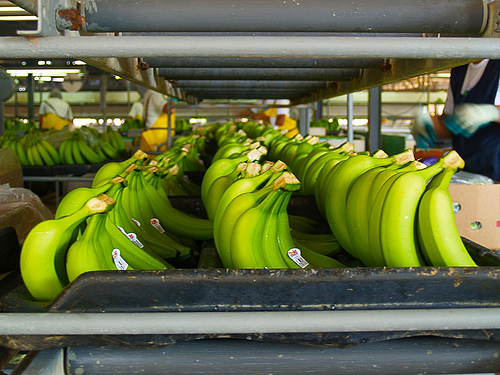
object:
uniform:
[442, 58, 500, 184]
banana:
[65, 196, 109, 284]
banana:
[113, 130, 127, 150]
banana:
[230, 176, 293, 269]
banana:
[324, 148, 413, 260]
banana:
[136, 153, 214, 241]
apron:
[263, 99, 299, 139]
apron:
[40, 100, 71, 130]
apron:
[139, 94, 176, 158]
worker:
[263, 99, 299, 139]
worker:
[137, 66, 176, 167]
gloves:
[410, 107, 438, 152]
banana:
[416, 157, 480, 267]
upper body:
[37, 97, 74, 119]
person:
[38, 88, 74, 131]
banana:
[31, 141, 44, 166]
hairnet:
[47, 87, 63, 99]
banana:
[54, 175, 126, 221]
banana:
[379, 150, 460, 269]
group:
[36, 57, 500, 184]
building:
[0, 0, 500, 130]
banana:
[262, 183, 294, 269]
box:
[448, 181, 500, 251]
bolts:
[470, 221, 483, 231]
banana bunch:
[367, 149, 478, 269]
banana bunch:
[19, 193, 135, 303]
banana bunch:
[212, 170, 313, 270]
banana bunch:
[58, 132, 107, 165]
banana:
[19, 196, 109, 302]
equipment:
[40, 3, 500, 107]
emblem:
[287, 248, 310, 269]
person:
[409, 58, 499, 182]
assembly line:
[0, 100, 500, 350]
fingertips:
[440, 114, 472, 139]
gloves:
[440, 103, 500, 139]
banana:
[63, 135, 75, 165]